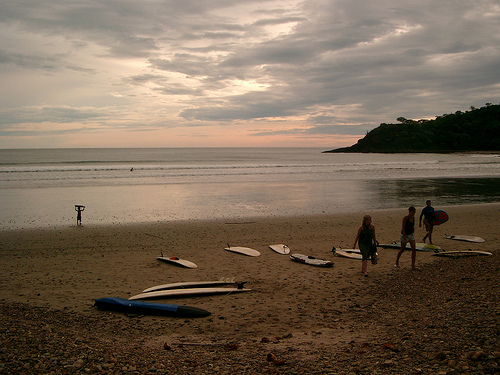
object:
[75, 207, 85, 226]
child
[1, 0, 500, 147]
sky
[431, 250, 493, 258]
surfboard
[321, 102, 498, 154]
trees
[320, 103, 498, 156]
hill.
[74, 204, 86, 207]
surf board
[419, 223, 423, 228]
hand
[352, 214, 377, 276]
man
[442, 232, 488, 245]
surfboards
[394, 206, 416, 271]
people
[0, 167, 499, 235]
shore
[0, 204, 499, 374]
sand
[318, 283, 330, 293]
footstep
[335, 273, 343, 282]
footstep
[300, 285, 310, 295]
footstep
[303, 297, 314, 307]
footstep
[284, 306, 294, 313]
footstep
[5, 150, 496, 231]
water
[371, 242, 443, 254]
board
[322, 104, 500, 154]
elevated area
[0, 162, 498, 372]
beach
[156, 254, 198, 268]
board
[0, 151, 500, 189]
crashing waves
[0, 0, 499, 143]
clouds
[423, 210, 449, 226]
surfboard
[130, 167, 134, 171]
person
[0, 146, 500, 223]
ocean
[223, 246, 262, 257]
board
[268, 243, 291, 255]
board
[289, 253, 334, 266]
board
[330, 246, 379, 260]
board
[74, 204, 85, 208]
board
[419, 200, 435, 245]
man